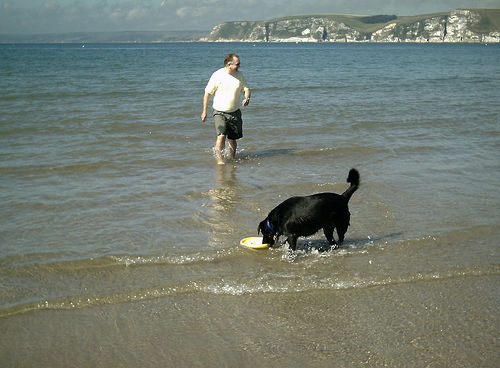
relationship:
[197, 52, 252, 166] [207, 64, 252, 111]
man wearing shirt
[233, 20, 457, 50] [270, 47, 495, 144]
rock cliff beside water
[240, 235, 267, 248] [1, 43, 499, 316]
disc in water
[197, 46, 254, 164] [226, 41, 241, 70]
man walking with hair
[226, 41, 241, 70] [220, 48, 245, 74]
hair on head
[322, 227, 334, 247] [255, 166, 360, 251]
legs on dog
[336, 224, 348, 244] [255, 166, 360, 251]
legs on dog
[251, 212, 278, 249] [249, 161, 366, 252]
head on dog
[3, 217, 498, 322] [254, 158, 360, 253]
waves by dog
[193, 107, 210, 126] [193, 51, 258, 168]
right hand on man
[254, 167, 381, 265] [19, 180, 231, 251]
dog in water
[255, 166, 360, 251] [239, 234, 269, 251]
dog grabbing disc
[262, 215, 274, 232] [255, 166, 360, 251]
collar on dog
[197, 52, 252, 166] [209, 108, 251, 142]
man wearing shorts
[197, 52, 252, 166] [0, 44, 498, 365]
man in water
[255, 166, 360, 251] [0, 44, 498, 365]
dog in water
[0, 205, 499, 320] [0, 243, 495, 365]
waves rolling onto shore